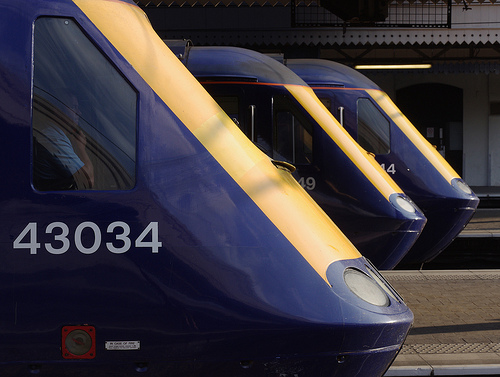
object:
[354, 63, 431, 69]
light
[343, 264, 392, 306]
head light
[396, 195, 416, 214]
head light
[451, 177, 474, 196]
head light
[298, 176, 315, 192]
numbers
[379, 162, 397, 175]
numbers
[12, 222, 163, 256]
numbers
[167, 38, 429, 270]
front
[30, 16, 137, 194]
window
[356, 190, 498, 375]
tracks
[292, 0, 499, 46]
grate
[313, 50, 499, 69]
awning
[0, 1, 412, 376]
train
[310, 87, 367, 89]
stripe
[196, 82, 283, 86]
stripe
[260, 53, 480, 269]
train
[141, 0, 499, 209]
building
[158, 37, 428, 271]
train